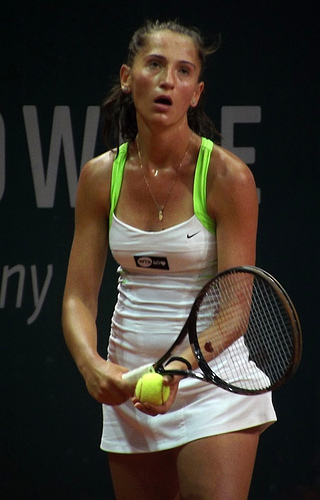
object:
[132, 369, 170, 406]
ball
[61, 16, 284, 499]
woman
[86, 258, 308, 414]
racket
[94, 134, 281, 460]
dress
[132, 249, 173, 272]
logo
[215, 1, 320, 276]
barrier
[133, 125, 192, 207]
chain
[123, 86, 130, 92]
earrings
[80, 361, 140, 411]
hand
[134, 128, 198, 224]
necklace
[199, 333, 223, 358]
tattoo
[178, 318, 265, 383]
forearm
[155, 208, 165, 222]
charm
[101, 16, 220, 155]
hair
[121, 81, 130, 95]
earlobe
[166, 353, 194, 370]
bracelet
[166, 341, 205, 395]
wrist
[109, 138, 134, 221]
green strap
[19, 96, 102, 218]
writing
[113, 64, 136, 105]
ear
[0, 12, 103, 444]
wall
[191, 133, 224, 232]
strap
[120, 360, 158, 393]
handle